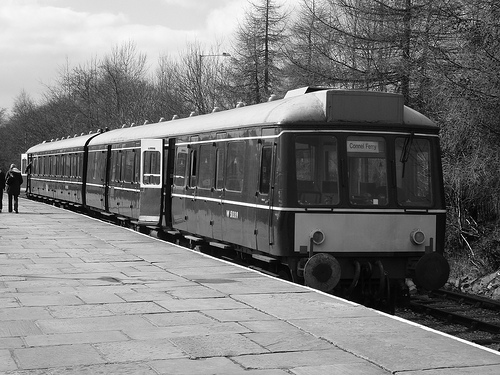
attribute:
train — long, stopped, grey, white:
[12, 78, 460, 293]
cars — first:
[80, 80, 451, 304]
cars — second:
[11, 124, 95, 213]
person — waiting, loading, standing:
[4, 159, 27, 216]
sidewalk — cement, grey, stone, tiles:
[0, 186, 498, 374]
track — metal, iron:
[399, 273, 499, 336]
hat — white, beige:
[10, 166, 23, 177]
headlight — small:
[406, 225, 431, 250]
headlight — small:
[310, 229, 328, 246]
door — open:
[137, 137, 166, 230]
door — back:
[17, 153, 31, 191]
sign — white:
[346, 136, 381, 155]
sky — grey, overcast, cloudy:
[1, 2, 499, 121]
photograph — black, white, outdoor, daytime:
[3, 1, 498, 374]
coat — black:
[3, 167, 26, 199]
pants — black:
[7, 187, 21, 213]